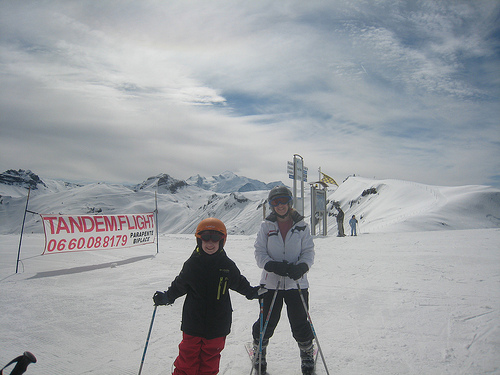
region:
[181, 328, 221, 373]
Red pants worn by the kid.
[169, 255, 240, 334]
Black coat worn by the kid.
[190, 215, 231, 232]
Orange helmet worn by the kid.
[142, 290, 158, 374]
Left ski pole held by the kid.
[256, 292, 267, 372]
Right ski pole held by the kid.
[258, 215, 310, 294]
White coat worn by the adult.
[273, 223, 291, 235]
Pink shirt worn by the adult.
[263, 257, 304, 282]
Black gloves worn by the adult.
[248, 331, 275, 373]
Left ski boot worn by the adult.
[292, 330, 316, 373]
Right ski boot worn by the woman.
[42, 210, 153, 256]
white banner with red and black writing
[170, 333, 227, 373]
skier in red pants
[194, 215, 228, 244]
skier with orange helmet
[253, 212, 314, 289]
woman in white coat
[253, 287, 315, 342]
woman wearing black pants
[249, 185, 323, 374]
woman standing behind kid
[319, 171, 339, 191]
yellow flag above sign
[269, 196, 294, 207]
dark goggles on woman's face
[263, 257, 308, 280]
woman wearing black gloves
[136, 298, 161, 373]
child holding ski pole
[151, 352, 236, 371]
Person wearing red pants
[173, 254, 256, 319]
Person wearing black jacket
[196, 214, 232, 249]
Orange helmet on person's head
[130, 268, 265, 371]
Person holding two poles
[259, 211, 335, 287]
Person wearing white jacket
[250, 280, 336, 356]
Person wearing black pants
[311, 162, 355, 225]
Yellow and black checkered flag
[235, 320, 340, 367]
Person wearing ski boots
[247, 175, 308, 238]
Helmet on person's head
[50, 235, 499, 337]
Snow covering ground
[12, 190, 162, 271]
Sign says Tandem Flight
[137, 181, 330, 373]
People are holding ski poles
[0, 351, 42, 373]
Handle of ski pole is in corner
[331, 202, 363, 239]
People are at signs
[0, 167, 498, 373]
Mountain is covered in snow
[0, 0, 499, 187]
Sky is cloudy and blue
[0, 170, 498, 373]
The snow is white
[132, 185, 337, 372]
People are wearing helmets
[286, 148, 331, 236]
Signs are behind people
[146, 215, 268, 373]
Person is wearing black coat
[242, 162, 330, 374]
person in white snow jacket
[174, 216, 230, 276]
orange helmet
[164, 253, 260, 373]
black snow jacket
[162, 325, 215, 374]
red snow pants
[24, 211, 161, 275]
white banner with red words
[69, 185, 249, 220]
snow on mountain top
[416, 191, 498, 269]
mound of snow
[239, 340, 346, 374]
skis with snow boots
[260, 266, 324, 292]
black gloves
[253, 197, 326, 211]
black snow googles with red lens